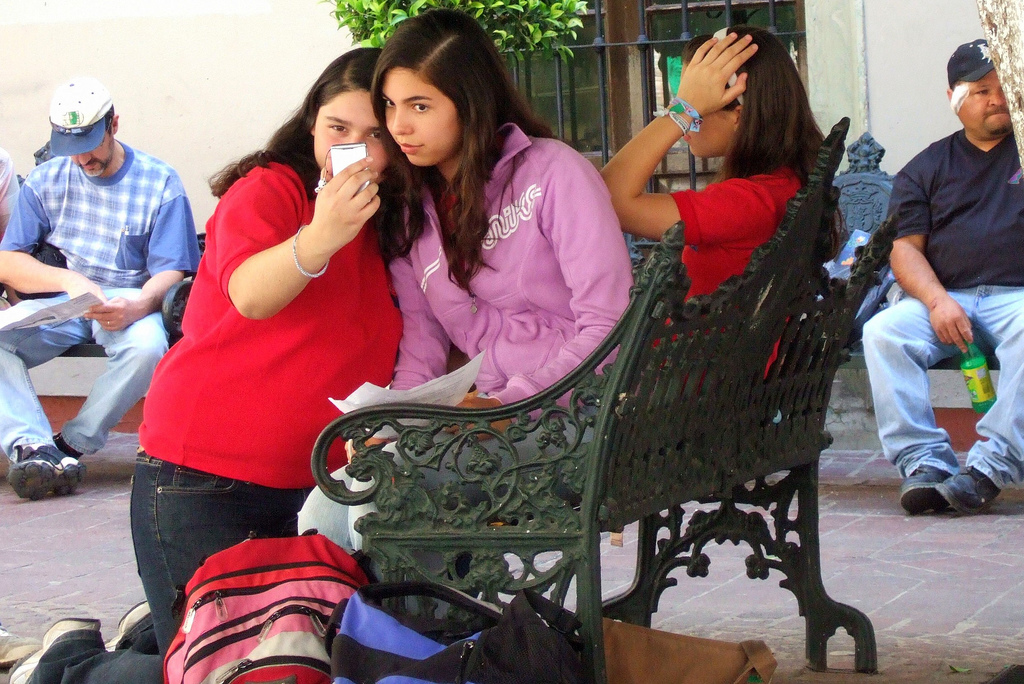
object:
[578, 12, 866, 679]
people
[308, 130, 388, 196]
cell phone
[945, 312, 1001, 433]
bottle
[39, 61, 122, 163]
hat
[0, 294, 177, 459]
pair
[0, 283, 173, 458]
jeans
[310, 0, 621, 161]
tree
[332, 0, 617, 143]
tree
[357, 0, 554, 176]
head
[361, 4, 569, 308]
hair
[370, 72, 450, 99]
forehead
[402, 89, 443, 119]
eyes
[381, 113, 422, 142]
nose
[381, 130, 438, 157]
mouth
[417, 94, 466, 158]
cheek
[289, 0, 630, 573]
girl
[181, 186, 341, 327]
arm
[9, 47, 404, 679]
girl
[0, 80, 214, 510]
person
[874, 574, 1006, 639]
stone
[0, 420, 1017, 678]
floor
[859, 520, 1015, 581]
stone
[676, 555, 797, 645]
stone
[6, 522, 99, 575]
stone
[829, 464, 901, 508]
stone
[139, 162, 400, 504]
shirt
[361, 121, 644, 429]
shirt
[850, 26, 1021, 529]
man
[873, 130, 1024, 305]
shirt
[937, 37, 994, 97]
hat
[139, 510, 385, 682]
backpack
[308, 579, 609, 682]
backpack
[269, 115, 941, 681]
bench